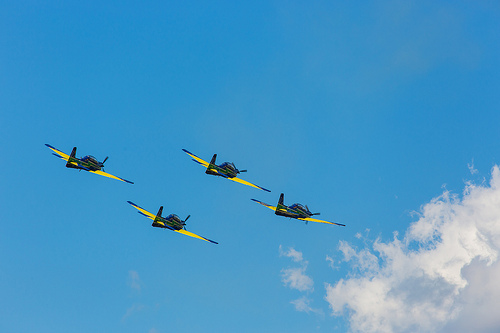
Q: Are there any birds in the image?
A: No, there are no birds.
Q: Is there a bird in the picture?
A: No, there are no birds.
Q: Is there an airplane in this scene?
A: Yes, there is an airplane.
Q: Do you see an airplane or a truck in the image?
A: Yes, there is an airplane.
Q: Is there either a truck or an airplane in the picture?
A: Yes, there is an airplane.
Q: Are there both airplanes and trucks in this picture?
A: No, there is an airplane but no trucks.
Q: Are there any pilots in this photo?
A: No, there are no pilots.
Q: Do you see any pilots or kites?
A: No, there are no pilots or kites.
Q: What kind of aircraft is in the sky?
A: The aircraft is an airplane.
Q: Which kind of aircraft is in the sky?
A: The aircraft is an airplane.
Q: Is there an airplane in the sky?
A: Yes, there is an airplane in the sky.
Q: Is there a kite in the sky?
A: No, there is an airplane in the sky.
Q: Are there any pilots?
A: No, there are no pilots.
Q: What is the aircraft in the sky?
A: The aircraft is a jet.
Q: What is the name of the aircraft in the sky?
A: The aircraft is a jet.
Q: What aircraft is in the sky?
A: The aircraft is a jet.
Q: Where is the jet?
A: The jet is in the sky.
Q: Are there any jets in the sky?
A: Yes, there is a jet in the sky.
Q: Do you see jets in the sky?
A: Yes, there is a jet in the sky.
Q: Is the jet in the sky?
A: Yes, the jet is in the sky.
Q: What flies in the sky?
A: The jet flies in the sky.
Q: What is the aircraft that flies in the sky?
A: The aircraft is a jet.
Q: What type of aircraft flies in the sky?
A: The aircraft is a jet.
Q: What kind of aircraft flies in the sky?
A: The aircraft is a jet.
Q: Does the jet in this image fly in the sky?
A: Yes, the jet flies in the sky.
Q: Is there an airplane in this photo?
A: Yes, there is an airplane.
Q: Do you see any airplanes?
A: Yes, there is an airplane.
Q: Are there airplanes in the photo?
A: Yes, there is an airplane.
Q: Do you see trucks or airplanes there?
A: Yes, there is an airplane.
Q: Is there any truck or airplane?
A: Yes, there is an airplane.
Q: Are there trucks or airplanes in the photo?
A: Yes, there is an airplane.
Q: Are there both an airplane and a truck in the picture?
A: No, there is an airplane but no trucks.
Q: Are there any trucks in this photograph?
A: No, there are no trucks.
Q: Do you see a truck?
A: No, there are no trucks.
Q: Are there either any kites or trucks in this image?
A: No, there are no trucks or kites.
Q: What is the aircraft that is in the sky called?
A: The aircraft is an airplane.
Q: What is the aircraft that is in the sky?
A: The aircraft is an airplane.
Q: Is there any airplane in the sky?
A: Yes, there is an airplane in the sky.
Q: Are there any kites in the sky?
A: No, there is an airplane in the sky.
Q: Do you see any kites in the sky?
A: No, there is an airplane in the sky.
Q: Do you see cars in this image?
A: No, there are no cars.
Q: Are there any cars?
A: No, there are no cars.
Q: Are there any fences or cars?
A: No, there are no cars or fences.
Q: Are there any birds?
A: No, there are no birds.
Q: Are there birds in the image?
A: No, there are no birds.